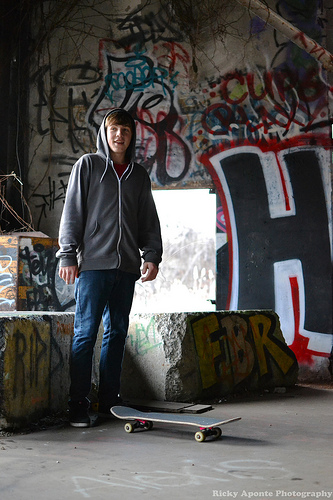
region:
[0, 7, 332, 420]
cement walls covered in grafitti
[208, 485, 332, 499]
name of photographer in corner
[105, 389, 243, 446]
skateboard not in use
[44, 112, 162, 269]
young boy wearing a grey hoodie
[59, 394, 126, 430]
white soled sneakers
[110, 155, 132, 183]
red shirt under hoodie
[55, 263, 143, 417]
blue jeans wrinkled at the knee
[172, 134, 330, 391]
a gigantic letter H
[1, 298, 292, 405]
raised cement platform with crumbling corners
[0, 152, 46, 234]
tangle on barbed wire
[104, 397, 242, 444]
the skateboard on the ground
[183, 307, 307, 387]
graffiti on the concrete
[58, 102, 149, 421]
the boy is standing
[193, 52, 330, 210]
large graffiti on the wall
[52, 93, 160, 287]
the boy is wearing hoodie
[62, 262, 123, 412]
the boy wearing jeans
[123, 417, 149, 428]
rear wheels on the skateboard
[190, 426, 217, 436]
front wheels on the skateboard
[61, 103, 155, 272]
the hoodie is gray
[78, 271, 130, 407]
the jeans are blue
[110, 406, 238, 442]
A skate board with wheels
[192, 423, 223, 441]
Front wheels of board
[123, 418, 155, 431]
Back wheels of board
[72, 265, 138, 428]
Dark blue jean pants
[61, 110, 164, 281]
Man in grey hoodie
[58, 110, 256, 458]
Skater about to skate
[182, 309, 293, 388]
Graffiti on concrete wall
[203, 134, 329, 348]
Graffiti H on wall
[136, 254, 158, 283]
A mans left hand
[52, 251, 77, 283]
A mans right hand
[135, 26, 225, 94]
graffiti is on the wall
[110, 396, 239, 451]
the board is black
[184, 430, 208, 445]
the wheel is white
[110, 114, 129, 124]
the hair is brown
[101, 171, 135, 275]
the hoodie has a zipper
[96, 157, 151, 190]
the hood has strings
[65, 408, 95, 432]
the shoe is black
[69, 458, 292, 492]
alexis is written on the ground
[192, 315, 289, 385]
different colored graffiti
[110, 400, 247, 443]
a long black skateboard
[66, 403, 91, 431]
the shoe of a boy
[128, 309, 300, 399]
a large gray stone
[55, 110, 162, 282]
a boy's gray hoodie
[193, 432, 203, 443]
a white skateboard wheel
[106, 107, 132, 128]
part of a boy's brown hair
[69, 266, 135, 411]
a boy's blue jean pants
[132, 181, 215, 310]
an open doorway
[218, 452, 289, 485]
a large white capital letter